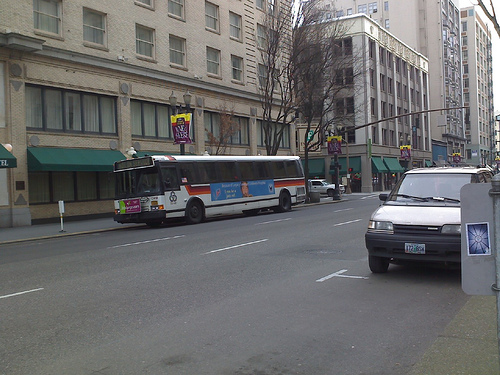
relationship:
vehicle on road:
[362, 161, 481, 274] [2, 166, 487, 374]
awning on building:
[31, 147, 128, 171] [15, 12, 348, 243]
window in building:
[187, 42, 247, 94] [21, 14, 298, 160]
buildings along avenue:
[78, 5, 395, 174] [0, 0, 496, 371]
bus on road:
[111, 150, 307, 225] [0, 192, 500, 374]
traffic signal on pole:
[462, 100, 474, 126] [324, 103, 469, 138]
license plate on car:
[404, 243, 426, 253] [366, 165, 495, 273]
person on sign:
[240, 182, 250, 194] [213, 180, 275, 200]